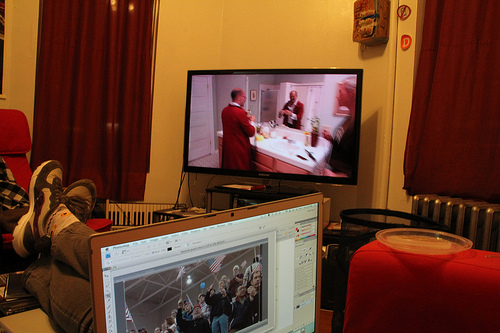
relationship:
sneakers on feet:
[11, 159, 97, 256] [11, 156, 99, 257]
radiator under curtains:
[407, 195, 499, 253] [402, 2, 499, 202]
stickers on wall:
[396, 2, 413, 52] [9, 2, 426, 223]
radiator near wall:
[407, 195, 499, 253] [9, 2, 426, 223]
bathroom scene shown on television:
[188, 73, 356, 178] [184, 68, 364, 186]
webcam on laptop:
[230, 210, 239, 217] [88, 190, 325, 331]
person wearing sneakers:
[11, 159, 101, 331] [11, 159, 97, 256]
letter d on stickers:
[401, 37, 412, 48] [396, 2, 413, 52]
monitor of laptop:
[101, 202, 317, 331] [88, 190, 325, 331]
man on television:
[219, 89, 257, 172] [184, 68, 364, 186]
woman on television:
[321, 75, 357, 177] [184, 68, 364, 186]